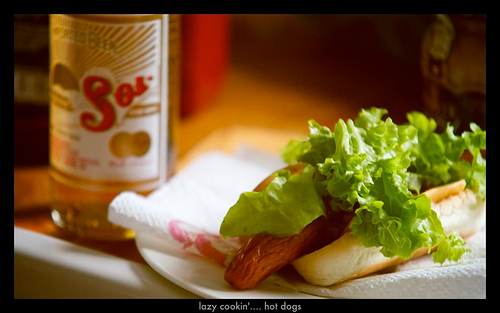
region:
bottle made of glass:
[45, 8, 192, 264]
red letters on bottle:
[73, 69, 178, 159]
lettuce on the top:
[239, 86, 493, 276]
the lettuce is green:
[225, 111, 483, 271]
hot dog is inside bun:
[223, 154, 494, 305]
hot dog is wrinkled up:
[218, 223, 328, 283]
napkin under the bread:
[112, 145, 496, 305]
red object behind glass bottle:
[175, 9, 251, 133]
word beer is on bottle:
[85, 31, 130, 74]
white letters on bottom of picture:
[182, 277, 306, 311]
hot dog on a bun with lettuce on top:
[218, 103, 485, 285]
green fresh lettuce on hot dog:
[221, 108, 487, 262]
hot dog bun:
[290, 178, 478, 286]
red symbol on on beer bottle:
[77, 67, 150, 133]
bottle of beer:
[47, 1, 173, 247]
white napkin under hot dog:
[107, 146, 289, 270]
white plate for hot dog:
[129, 224, 329, 299]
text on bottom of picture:
[196, 300, 308, 312]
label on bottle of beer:
[46, 12, 167, 190]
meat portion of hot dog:
[221, 203, 335, 287]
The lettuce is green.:
[317, 117, 424, 204]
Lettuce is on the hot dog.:
[310, 112, 410, 177]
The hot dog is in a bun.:
[313, 218, 426, 273]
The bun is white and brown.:
[332, 229, 393, 283]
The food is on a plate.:
[124, 130, 486, 300]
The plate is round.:
[123, 141, 484, 298]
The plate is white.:
[126, 152, 484, 299]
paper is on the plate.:
[118, 132, 268, 237]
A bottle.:
[34, 10, 196, 257]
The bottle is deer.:
[32, 11, 194, 255]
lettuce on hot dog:
[305, 104, 469, 257]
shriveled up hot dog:
[224, 184, 349, 297]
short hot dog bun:
[283, 177, 481, 292]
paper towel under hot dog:
[127, 145, 259, 261]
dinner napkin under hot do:
[113, 142, 320, 275]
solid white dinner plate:
[128, 205, 315, 299]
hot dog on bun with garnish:
[206, 109, 486, 291]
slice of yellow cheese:
[398, 165, 475, 217]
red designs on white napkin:
[155, 202, 243, 273]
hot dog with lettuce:
[197, 91, 498, 305]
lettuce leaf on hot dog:
[212, 153, 334, 250]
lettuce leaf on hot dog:
[320, 113, 418, 195]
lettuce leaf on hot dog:
[270, 111, 342, 168]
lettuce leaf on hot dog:
[340, 166, 469, 298]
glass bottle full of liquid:
[37, 0, 206, 254]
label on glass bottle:
[32, 5, 181, 190]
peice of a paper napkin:
[94, 136, 288, 261]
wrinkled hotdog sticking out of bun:
[207, 210, 334, 297]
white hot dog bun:
[292, 181, 484, 303]